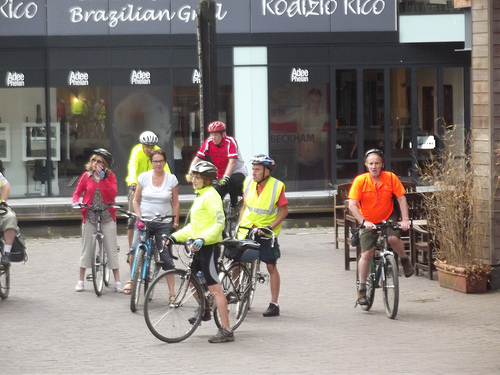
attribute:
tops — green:
[164, 173, 290, 245]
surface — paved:
[0, 327, 497, 371]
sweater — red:
[69, 168, 130, 219]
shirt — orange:
[345, 170, 410, 227]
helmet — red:
[207, 121, 227, 138]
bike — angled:
[142, 237, 262, 343]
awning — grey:
[0, 0, 398, 42]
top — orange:
[341, 166, 408, 226]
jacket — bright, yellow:
[124, 142, 170, 185]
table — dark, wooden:
[342, 187, 457, 274]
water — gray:
[20, 211, 421, 233]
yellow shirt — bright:
[158, 184, 237, 251]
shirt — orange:
[337, 144, 432, 326]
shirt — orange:
[347, 172, 405, 224]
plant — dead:
[377, 108, 497, 289]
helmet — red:
[208, 120, 226, 131]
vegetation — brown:
[419, 138, 491, 299]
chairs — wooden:
[333, 183, 359, 270]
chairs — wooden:
[410, 217, 435, 282]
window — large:
[2, 48, 229, 196]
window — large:
[269, 42, 459, 187]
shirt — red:
[192, 132, 241, 189]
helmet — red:
[205, 120, 231, 135]